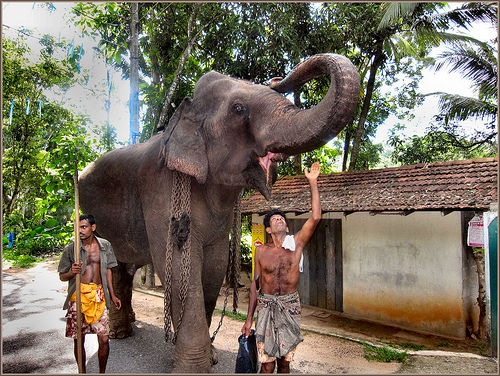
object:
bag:
[232, 331, 258, 373]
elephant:
[77, 52, 361, 374]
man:
[240, 161, 330, 376]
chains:
[235, 186, 242, 310]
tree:
[0, 24, 59, 252]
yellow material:
[69, 282, 105, 321]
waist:
[70, 278, 102, 293]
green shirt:
[58, 234, 118, 309]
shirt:
[283, 233, 308, 275]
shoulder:
[284, 233, 298, 246]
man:
[53, 215, 124, 375]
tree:
[413, 2, 499, 173]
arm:
[297, 178, 324, 246]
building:
[233, 157, 497, 356]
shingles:
[274, 262, 294, 284]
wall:
[238, 207, 500, 348]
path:
[1, 249, 498, 372]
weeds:
[388, 351, 390, 352]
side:
[56, 239, 96, 350]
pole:
[66, 161, 86, 376]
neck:
[166, 103, 238, 222]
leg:
[164, 245, 213, 374]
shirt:
[248, 287, 303, 362]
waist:
[255, 289, 302, 303]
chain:
[157, 171, 194, 346]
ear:
[156, 90, 226, 185]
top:
[96, 1, 286, 58]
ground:
[0, 251, 500, 376]